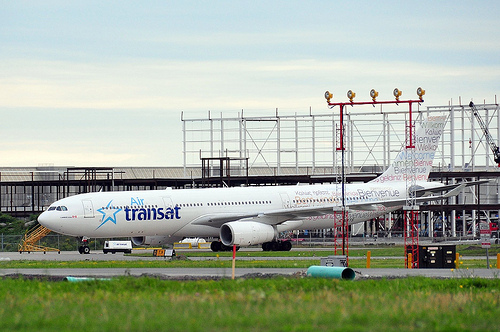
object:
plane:
[36, 114, 495, 254]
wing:
[262, 181, 465, 224]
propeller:
[220, 215, 274, 247]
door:
[83, 194, 95, 217]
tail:
[386, 109, 449, 184]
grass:
[0, 258, 499, 268]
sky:
[1, 0, 499, 166]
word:
[128, 195, 146, 207]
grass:
[1, 274, 497, 331]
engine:
[217, 217, 274, 247]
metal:
[403, 211, 417, 269]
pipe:
[304, 264, 354, 282]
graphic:
[97, 199, 124, 229]